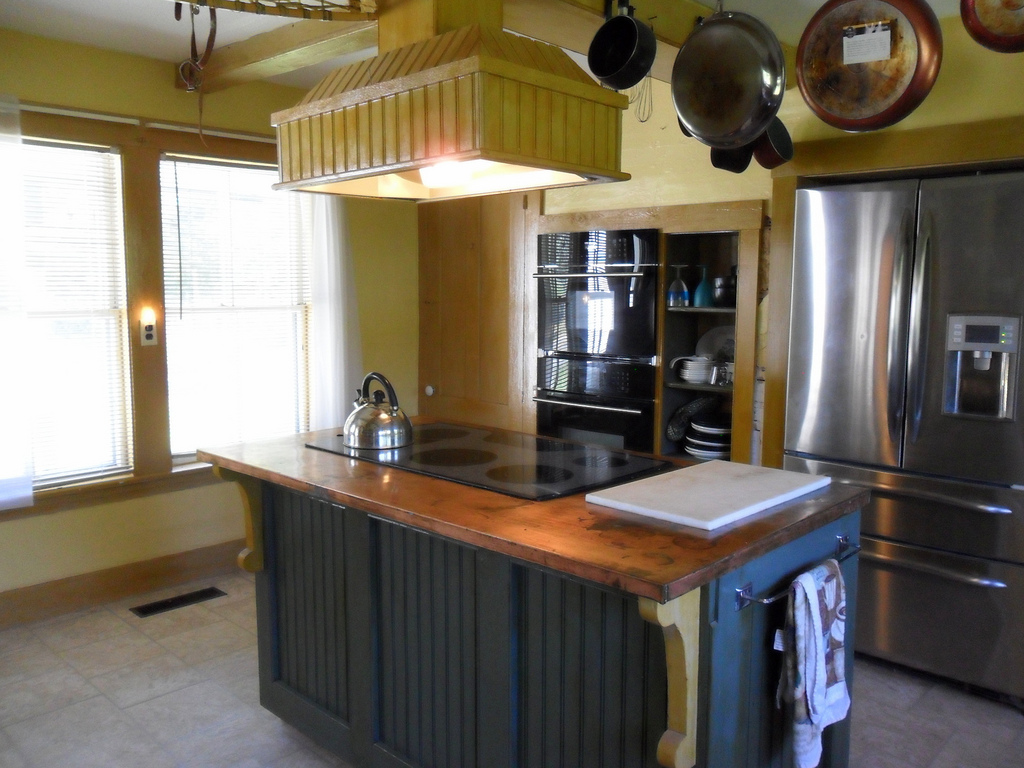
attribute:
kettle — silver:
[334, 366, 421, 466]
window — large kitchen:
[163, 153, 356, 468]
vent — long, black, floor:
[122, 569, 233, 623]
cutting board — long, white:
[582, 447, 835, 539]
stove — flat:
[304, 400, 668, 511]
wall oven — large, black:
[517, 221, 661, 469]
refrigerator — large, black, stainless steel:
[759, 168, 1022, 704]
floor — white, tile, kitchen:
[4, 537, 1022, 756]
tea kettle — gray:
[332, 362, 416, 464]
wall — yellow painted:
[4, 0, 1017, 611]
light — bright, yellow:
[132, 296, 163, 331]